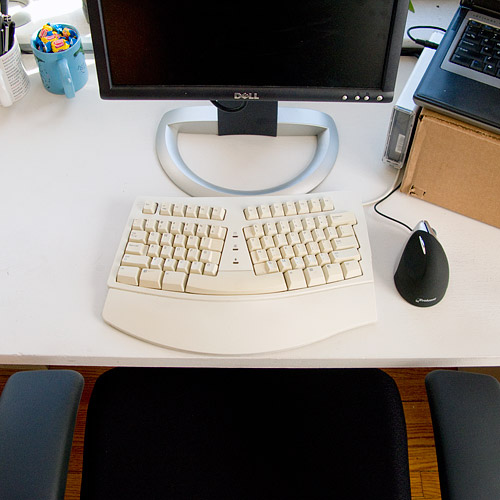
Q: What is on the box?
A: A laptop.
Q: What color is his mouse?
A: Black.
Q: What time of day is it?
A: Daytime.